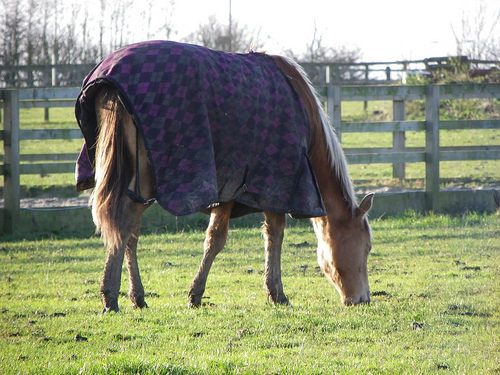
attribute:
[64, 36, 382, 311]
horse — eating, brown, grazing, big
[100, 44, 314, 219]
blanket — red, black, checked, grazing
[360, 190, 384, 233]
ear — brown, up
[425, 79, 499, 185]
fence — wooden, brown, gray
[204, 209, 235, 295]
leg — brown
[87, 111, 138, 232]
tail — brown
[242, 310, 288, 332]
grass — green, yellow, short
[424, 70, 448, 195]
post — wooden